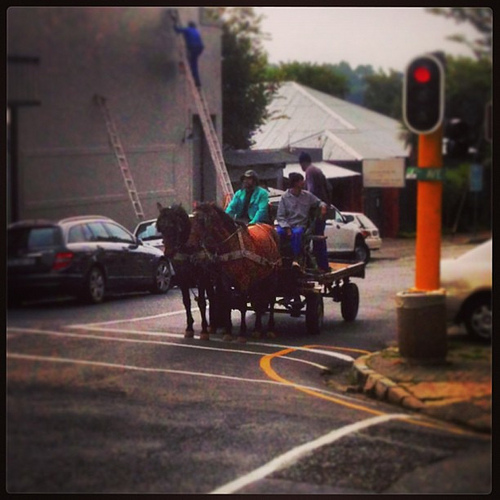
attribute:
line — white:
[206, 410, 421, 494]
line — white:
[8, 351, 379, 406]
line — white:
[6, 325, 328, 370]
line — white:
[62, 300, 355, 362]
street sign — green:
[407, 164, 447, 181]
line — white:
[15, 347, 290, 402]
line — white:
[204, 414, 414, 486]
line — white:
[70, 315, 190, 342]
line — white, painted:
[6, 365, 286, 388]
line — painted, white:
[103, 311, 190, 326]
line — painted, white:
[8, 323, 55, 339]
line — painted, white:
[259, 339, 355, 360]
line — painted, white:
[211, 415, 390, 494]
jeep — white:
[322, 207, 369, 264]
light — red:
[401, 53, 446, 133]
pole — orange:
[413, 127, 444, 292]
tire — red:
[83, 264, 111, 304]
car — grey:
[0, 210, 172, 313]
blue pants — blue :
[277, 226, 304, 253]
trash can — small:
[397, 286, 449, 365]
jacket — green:
[227, 185, 269, 222]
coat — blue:
[225, 184, 267, 223]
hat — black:
[240, 166, 260, 186]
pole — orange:
[409, 132, 439, 293]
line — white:
[10, 338, 177, 390]